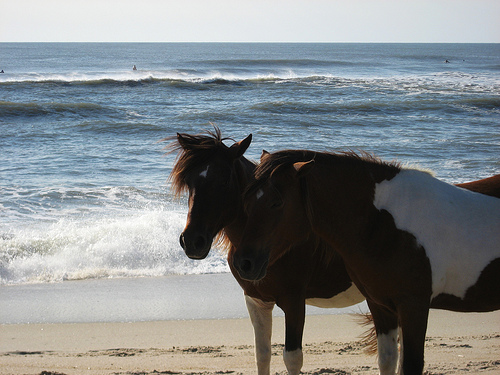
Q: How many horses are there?
A: Two.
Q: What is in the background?
A: Oceans.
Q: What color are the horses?
A: Brown and white.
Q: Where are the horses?
A: At the beach.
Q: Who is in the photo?
A: Horses.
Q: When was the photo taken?
A: Daytime.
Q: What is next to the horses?
A: Water.